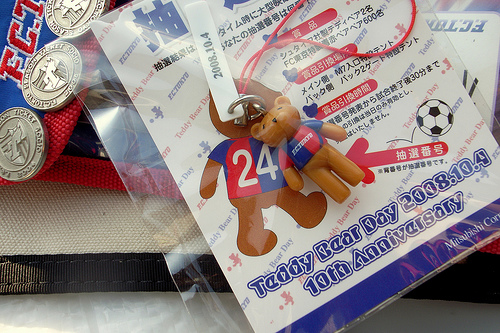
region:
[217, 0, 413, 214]
Small plastic bear on a key ring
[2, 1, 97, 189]
Row of three medals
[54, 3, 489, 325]
Bear inside clear plastic package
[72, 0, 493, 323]
Information card inside clear plastic packaging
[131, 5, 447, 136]
Foreign language written on a card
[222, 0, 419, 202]
Red plastic string attached to bear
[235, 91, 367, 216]
Bear painted with red and blue soccer jersey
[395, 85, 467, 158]
Picture of a soccer ball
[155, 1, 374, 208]
Bear with ID tag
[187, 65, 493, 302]
Card for Teddy Bear Day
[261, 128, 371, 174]
The bear has a red and blue shirt.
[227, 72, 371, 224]
The bear is brown.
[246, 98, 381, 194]
The bear is small.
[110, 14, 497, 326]
The bear is in a package.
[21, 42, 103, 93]
The coin is silver.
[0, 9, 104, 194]
Three coins are on the flap.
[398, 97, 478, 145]
The soccer ball is white and black.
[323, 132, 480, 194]
The arrow is red.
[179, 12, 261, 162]
The tax is white.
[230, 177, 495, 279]
The words are blue.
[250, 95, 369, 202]
Teddy bear on a red band.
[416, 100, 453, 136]
Soccer ball on a white, red and blue paper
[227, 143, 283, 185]
A white number 24 on a bear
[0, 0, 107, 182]
Three silver coins on the left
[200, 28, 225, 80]
2008.10.4 on a small white tab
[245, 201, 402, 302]
The words TEDDY BEAR DAY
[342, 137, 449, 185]
A red arrow with Chinese writing on it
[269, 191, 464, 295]
10th Anniversary below the bear.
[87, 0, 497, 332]
Red, white, blue and black paper with a bear on it wrapped in plastic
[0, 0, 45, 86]
E.C.T behind the coins on the left.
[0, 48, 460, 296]
teddy bear on a key chain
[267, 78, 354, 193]
small plastic teddy bear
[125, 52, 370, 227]
small key chain attachment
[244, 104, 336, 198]
white and blue shirt on bear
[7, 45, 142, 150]
small silver coins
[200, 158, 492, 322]
blue writing beneath bear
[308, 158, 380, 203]
legs of brown bear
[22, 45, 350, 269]
image of bear drawn behind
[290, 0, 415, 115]
red rope above head of bear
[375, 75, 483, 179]
soccer ball drawn on paper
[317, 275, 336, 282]
word 10th is written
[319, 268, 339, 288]
word 10th is written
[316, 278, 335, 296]
word 10th is written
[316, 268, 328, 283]
word 10th is written